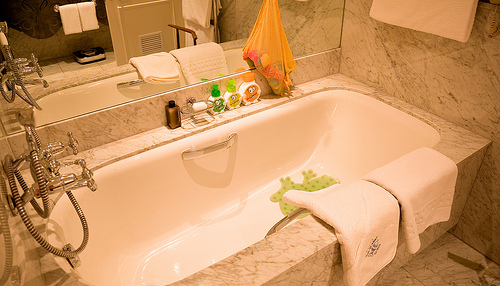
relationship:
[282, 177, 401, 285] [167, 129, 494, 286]
towel on edge of tub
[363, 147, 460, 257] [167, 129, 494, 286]
towel on edge of tub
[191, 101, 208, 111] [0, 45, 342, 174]
soap dish attached to wall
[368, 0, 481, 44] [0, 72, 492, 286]
towel hanging above bathtub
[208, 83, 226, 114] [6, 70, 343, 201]
bottle on side of tub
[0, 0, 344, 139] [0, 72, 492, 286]
mirror next to bathtub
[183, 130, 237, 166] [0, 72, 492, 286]
handle inside bathtub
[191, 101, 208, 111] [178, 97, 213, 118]
soap dish on soap tray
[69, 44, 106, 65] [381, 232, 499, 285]
reflection of scale on floor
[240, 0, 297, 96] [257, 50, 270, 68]
net with bath toy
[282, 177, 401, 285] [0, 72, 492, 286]
towel on bathtub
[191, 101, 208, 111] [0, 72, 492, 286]
soap by bathtub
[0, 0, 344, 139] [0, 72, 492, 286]
mirror by bathtub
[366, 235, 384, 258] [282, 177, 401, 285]
emblem on towel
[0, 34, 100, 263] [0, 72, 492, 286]
faucet on bathtub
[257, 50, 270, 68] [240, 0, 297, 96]
bath toy in bag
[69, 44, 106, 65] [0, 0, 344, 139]
reflection of scale in mirror